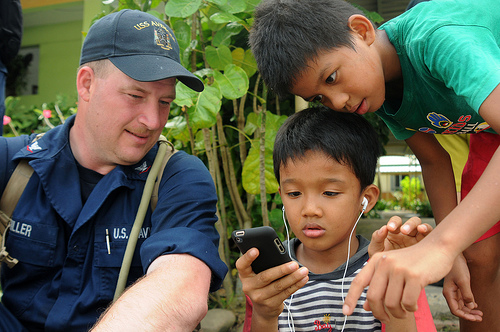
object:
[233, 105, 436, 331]
boy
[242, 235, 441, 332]
shirt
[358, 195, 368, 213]
earbuds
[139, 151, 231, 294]
sleeve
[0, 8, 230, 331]
sailor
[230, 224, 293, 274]
phone